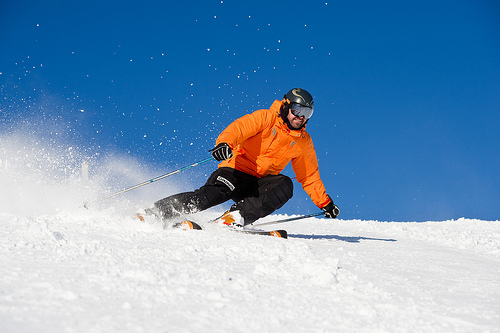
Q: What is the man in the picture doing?
A: Skiing.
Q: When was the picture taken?
A: Daytime.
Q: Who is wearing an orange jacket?
A: The skier.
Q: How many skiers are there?
A: One.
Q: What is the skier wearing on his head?
A: Helmet.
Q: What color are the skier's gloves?
A: Black and white.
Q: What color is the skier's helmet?
A: Black and yellow.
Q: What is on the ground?
A: Snow.